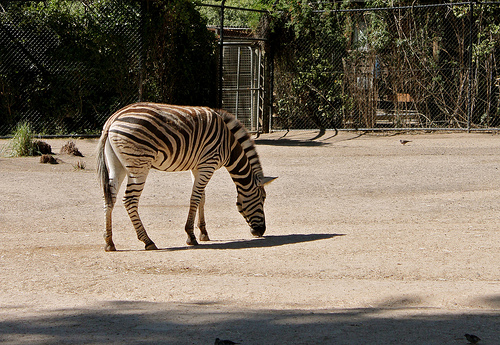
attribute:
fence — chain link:
[269, 0, 499, 130]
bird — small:
[395, 133, 409, 148]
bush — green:
[27, 3, 117, 15]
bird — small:
[393, 127, 415, 147]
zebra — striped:
[92, 93, 272, 251]